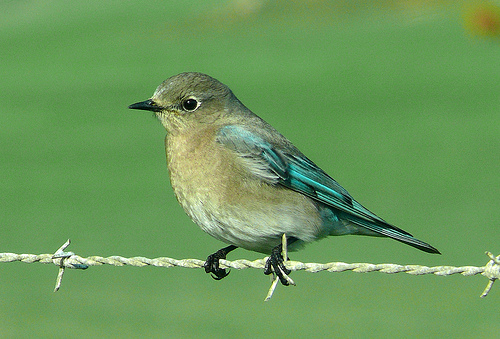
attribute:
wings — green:
[203, 102, 449, 261]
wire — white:
[1, 238, 498, 298]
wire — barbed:
[5, 243, 497, 304]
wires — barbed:
[31, 245, 151, 282]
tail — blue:
[329, 184, 445, 257]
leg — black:
[204, 244, 234, 283]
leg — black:
[263, 236, 293, 289]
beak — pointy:
[126, 98, 161, 115]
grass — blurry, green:
[4, 2, 496, 338]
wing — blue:
[239, 139, 424, 252]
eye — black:
[182, 97, 194, 110]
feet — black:
[191, 239, 311, 299]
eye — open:
[181, 97, 201, 113]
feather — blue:
[245, 136, 384, 221]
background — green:
[1, 1, 498, 336]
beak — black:
[124, 96, 168, 114]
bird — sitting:
[117, 61, 470, 282]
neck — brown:
[158, 122, 232, 169]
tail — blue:
[295, 166, 427, 257]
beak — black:
[127, 98, 164, 111]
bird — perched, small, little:
[116, 63, 448, 292]